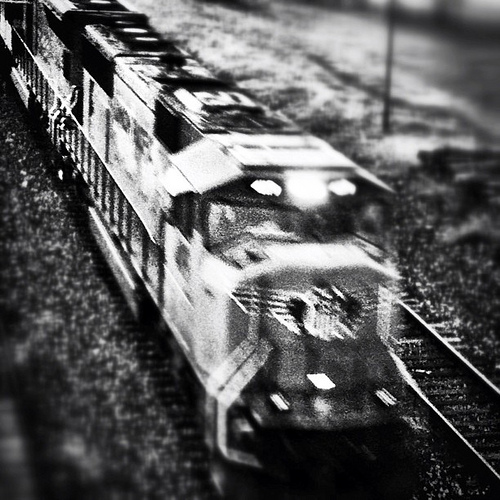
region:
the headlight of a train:
[248, 172, 288, 203]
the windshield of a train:
[201, 195, 310, 247]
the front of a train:
[188, 160, 432, 459]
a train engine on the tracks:
[66, 28, 457, 497]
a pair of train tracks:
[348, 251, 499, 490]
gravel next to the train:
[3, 131, 213, 487]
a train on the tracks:
[1, 0, 406, 482]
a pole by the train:
[373, 0, 401, 135]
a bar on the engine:
[201, 340, 280, 482]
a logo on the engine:
[286, 281, 371, 353]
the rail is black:
[431, 320, 488, 429]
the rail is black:
[393, 317, 483, 489]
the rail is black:
[395, 270, 457, 450]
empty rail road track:
[354, 227, 499, 479]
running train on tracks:
[180, 177, 387, 455]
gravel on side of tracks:
[5, 142, 174, 452]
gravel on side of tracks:
[291, 92, 491, 157]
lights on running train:
[236, 170, 363, 217]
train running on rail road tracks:
[36, 80, 474, 487]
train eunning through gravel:
[12, 80, 497, 497]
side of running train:
[21, 83, 201, 263]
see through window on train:
[200, 198, 377, 242]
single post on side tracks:
[362, 87, 402, 140]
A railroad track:
[422, 324, 499, 446]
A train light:
[245, 175, 302, 201]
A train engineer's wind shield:
[194, 190, 309, 257]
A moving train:
[68, 35, 483, 493]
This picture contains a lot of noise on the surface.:
[75, 53, 393, 471]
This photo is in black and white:
[60, 102, 395, 452]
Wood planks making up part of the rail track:
[438, 375, 474, 411]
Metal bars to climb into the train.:
[51, 87, 75, 154]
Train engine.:
[78, 33, 470, 441]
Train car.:
[8, 3, 65, 60]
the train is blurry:
[161, 256, 341, 452]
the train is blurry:
[222, 319, 368, 489]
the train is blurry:
[241, 277, 359, 444]